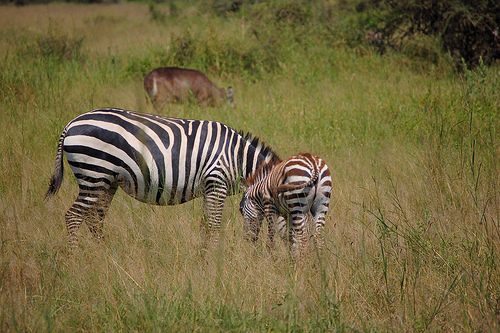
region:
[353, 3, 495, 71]
dark green bush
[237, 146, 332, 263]
small zebra grazing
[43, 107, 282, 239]
large zebra grazing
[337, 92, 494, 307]
tall green and yellow grass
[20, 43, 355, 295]
three animals grazing in the tall grass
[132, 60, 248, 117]
brown and white animal grazing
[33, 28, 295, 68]
green scrubby bushes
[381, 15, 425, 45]
branches of small tree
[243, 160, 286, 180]
brown and white mane of small zebra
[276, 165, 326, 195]
small zebra's tail swinging left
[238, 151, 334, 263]
zebra standing in grassy field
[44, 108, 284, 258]
zebra standing in grassy field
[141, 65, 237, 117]
brown animal standing in grassy field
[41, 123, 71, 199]
zebra's tail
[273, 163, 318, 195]
zebra's tail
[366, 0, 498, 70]
bush growing near grassy field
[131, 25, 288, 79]
bush growing in grassy field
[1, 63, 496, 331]
grassy field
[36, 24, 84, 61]
bush growing in grassy field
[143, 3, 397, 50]
bushes growing in grassy field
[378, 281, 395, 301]
part of the grass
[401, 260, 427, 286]
part of a bush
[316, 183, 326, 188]
back of a zebra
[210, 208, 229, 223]
leg of a zebra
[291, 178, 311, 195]
part of a zebra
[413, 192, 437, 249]
edge of a bush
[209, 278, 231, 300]
part of a plain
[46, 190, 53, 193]
tail of a zebra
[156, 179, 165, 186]
part of a zebra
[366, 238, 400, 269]
edge of a bush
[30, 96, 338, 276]
two zebras in a field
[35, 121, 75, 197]
long tail of zebra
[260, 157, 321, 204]
the tail of zebra is in motion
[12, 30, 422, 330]
the mane of zebra is white and black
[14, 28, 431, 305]
wild animals in the meadow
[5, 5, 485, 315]
grass of field is green and brown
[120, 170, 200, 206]
belly of zebra is bulky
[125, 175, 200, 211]
belly of zebra is striped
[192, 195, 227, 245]
front legs of zebra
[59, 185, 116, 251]
back legs of zebra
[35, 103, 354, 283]
a pair of zebras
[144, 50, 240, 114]
and animal grazing in the field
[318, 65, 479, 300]
tall green grass in the field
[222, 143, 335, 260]
a baby zebra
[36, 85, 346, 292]
a mother zebra and her foal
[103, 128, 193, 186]
black and white stripes on a zebra's side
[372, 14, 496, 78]
dark shadows under a tree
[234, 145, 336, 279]
a baby zebra grazing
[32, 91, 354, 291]
two zebras grazing in a field